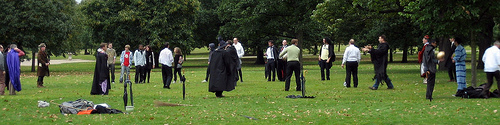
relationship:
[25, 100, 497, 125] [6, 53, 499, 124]
leaves on ground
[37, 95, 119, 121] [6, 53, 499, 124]
clothes on ground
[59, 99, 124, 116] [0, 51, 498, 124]
clothes on grass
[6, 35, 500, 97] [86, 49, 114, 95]
person in garment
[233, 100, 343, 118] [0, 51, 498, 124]
flowers on grass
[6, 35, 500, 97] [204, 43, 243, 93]
man wearing robe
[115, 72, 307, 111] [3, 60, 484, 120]
umbrella in ground